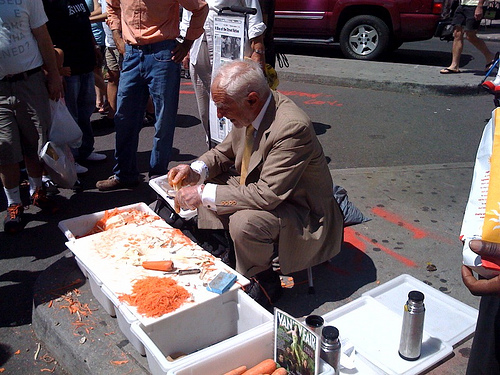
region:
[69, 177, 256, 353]
carrots on white cutting board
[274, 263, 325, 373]
vanity fair magazine in box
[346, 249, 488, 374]
stainless steel thermos on white board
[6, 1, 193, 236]
spectators watching man cut carrots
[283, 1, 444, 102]
marroon vehicle in background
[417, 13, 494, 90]
woman walking in black flip flops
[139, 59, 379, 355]
man in tan suit cutting carrots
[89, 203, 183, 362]
carrots on white cutting board on top of white boxes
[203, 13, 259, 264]
white newspaper article on display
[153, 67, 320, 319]
man in tan suit and yellow tie sitting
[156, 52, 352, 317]
a man in a tan suit peeling a carrot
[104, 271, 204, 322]
shredded carrots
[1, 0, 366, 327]
people watching the man demonstrating something with carrots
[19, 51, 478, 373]
the man is on the sidewalk at a street corner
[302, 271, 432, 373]
three silver thermos bottles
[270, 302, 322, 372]
a Vanity Fair magazine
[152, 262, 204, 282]
a carrot peeler on the table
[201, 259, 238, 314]
a blue sponge on the table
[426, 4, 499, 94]
a man wearing shorts and flip flops is walking in the background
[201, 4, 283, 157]
a newspaper is displayed in the background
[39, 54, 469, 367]
a man giving a demonstration in the road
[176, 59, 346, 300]
a man in a suit domonstrates a product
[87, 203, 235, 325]
shaved carrots on a cutting board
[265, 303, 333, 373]
a copy of vanity fair is displayed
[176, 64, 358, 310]
the man sits on a stool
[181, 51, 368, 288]
the man is wearing a tan suit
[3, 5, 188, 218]
people watch the man with the carrots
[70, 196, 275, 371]
white bins are under the chopping block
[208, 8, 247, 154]
a white news article is hanging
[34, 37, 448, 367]
a man is performing on a sidewalk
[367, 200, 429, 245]
pink paint on ground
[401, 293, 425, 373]
large shiny black and silver bottle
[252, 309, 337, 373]
green and white magazine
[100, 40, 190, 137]
man wearing blue jeans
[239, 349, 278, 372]
orange pencils in container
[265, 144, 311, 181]
wrinkles in man's brown suit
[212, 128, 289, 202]
gold tie around man's neck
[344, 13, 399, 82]
black and silver wheel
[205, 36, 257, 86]
bald spot on man's head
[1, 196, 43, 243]
blue and orange sneakers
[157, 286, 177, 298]
peeled pink carrots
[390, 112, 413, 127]
section of a road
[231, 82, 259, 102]
head of a old man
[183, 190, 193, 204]
left hand of a man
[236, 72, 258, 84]
section of white hair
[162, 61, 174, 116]
section of blue jeans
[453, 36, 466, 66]
right leg of a man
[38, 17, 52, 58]
left hand of man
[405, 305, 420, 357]
part of a flask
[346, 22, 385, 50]
back wheel of a car